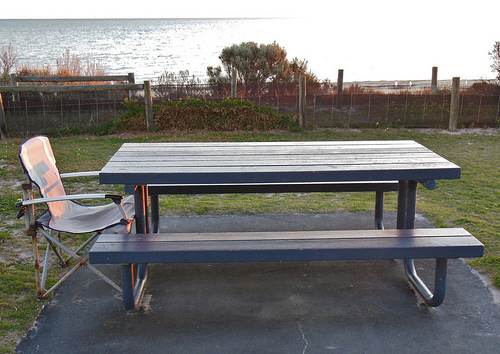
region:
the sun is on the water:
[133, 17, 398, 75]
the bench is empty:
[16, 79, 486, 303]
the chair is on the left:
[0, 110, 150, 274]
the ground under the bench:
[176, 260, 403, 338]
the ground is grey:
[159, 265, 419, 352]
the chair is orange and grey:
[4, 117, 148, 313]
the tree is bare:
[141, 46, 210, 106]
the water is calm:
[26, 19, 191, 73]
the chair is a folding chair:
[0, 131, 160, 314]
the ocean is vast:
[18, 2, 174, 64]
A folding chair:
[17, 134, 134, 301]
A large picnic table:
[87, 136, 479, 313]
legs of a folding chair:
[37, 225, 126, 301]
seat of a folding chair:
[37, 193, 134, 233]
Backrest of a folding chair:
[15, 134, 67, 220]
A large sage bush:
[205, 42, 309, 93]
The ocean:
[0, 17, 499, 84]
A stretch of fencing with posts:
[1, 74, 498, 133]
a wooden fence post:
[141, 79, 152, 130]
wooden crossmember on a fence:
[14, 73, 127, 83]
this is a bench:
[86, 220, 488, 326]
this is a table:
[71, 122, 482, 233]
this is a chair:
[5, 131, 137, 299]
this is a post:
[444, 73, 465, 129]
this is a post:
[409, 47, 444, 122]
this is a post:
[330, 55, 360, 136]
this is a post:
[217, 45, 259, 112]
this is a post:
[133, 62, 174, 124]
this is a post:
[0, 75, 147, 102]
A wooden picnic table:
[85, 136, 483, 313]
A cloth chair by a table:
[16, 133, 151, 306]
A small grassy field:
[0, 135, 499, 351]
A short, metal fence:
[2, 89, 499, 131]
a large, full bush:
[206, 41, 321, 92]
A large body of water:
[2, 18, 421, 95]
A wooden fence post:
[142, 79, 157, 129]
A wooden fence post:
[296, 76, 310, 127]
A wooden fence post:
[447, 75, 462, 133]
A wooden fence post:
[430, 65, 438, 95]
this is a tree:
[204, 32, 328, 114]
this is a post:
[270, 68, 327, 137]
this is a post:
[437, 54, 486, 144]